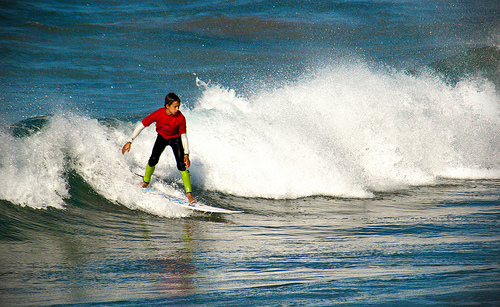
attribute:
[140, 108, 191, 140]
shirt — red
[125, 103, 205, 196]
suit — white, black, yellow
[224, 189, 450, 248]
blue water — dark blue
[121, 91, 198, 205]
boy — surfing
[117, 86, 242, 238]
boy — surfing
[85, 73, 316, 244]
boy — black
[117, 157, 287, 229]
surfboard — white 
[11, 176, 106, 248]
water — blue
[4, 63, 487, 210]
wave — blue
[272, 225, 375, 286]
water — dark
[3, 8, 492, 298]
water — dark blue, dark, blue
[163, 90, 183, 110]
hair — short